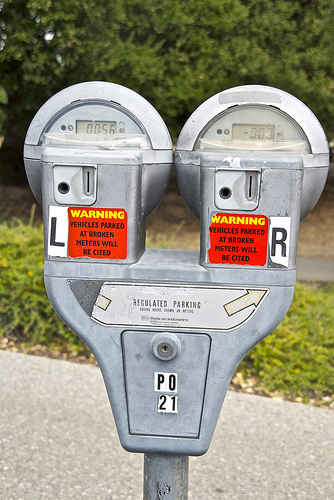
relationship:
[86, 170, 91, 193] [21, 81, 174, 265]
slot on parking meter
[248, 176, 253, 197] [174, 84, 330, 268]
slot on parking meter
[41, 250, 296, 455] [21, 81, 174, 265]
container under parking meter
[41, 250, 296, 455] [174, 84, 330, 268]
container under parking meter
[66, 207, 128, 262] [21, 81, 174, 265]
sticker on parking meter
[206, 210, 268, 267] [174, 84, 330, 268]
sticker on parking meter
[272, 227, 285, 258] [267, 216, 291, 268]
r on sticker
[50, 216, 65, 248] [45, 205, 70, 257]
l on sticker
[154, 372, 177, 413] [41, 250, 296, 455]
sticker on container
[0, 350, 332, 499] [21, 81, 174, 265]
concrete behind parking meter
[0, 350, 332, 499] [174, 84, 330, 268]
concrete behind parking meter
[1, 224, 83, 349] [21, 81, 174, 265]
grass behind parking meter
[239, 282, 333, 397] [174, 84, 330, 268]
grass behind parking meter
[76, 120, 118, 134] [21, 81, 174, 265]
display on parking meter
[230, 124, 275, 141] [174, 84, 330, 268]
display on parking meter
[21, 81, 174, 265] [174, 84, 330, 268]
parking meter next to parking meter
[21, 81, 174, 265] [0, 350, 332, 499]
parking meter next to concrete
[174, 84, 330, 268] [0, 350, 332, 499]
parking meter next to concrete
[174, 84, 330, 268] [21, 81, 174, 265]
parking meter to right of parking meter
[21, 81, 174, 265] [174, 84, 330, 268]
parking meter to left of parking meter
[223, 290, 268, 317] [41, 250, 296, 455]
arrow on container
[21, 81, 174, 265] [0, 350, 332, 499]
parking meter near concrete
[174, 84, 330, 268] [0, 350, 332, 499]
parking meter near concrete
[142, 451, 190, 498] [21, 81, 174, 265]
pole holding parking meter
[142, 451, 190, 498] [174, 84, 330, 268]
pole holding parking meter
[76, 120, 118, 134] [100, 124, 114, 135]
display shows time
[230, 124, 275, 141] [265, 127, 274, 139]
display shows time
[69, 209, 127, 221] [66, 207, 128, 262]
word on sticker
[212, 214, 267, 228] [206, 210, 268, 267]
word on sticker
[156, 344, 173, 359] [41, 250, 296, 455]
key hole on container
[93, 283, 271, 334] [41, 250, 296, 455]
sign on container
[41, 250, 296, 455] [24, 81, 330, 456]
container of double meter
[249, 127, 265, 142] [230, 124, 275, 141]
digits on display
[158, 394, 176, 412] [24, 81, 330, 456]
number on double meter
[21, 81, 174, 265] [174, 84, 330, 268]
parking meter left of parking meter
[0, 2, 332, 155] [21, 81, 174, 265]
trees behind parking meter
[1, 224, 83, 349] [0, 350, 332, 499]
grass lining concrete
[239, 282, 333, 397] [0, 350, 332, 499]
grass lining concrete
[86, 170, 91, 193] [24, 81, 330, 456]
slot on double meter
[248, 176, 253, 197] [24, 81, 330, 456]
slot on double meter